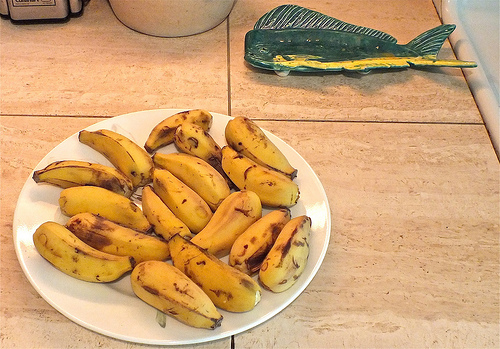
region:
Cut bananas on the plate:
[40, 123, 312, 323]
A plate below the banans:
[46, 108, 326, 320]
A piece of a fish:
[243, 8, 473, 75]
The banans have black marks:
[262, 217, 316, 286]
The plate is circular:
[31, 114, 329, 328]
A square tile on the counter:
[228, 116, 498, 343]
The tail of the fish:
[407, 26, 477, 75]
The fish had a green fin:
[253, 4, 400, 39]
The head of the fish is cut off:
[219, 30, 253, 64]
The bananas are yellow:
[31, 110, 322, 330]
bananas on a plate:
[7, 103, 342, 347]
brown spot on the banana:
[230, 201, 253, 219]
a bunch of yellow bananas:
[29, 111, 314, 334]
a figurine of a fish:
[238, 6, 476, 77]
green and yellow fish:
[240, 5, 481, 86]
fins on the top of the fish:
[253, 1, 403, 42]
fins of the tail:
[408, 17, 479, 79]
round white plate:
[9, 106, 332, 347]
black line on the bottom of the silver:
[1, 7, 94, 26]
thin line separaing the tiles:
[230, 109, 488, 127]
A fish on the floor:
[241, 7, 482, 72]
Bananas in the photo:
[30, 110, 300, 320]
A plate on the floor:
[75, 285, 120, 325]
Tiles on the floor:
[331, 128, 461, 246]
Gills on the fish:
[262, 4, 375, 36]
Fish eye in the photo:
[257, 44, 269, 54]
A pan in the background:
[105, 6, 231, 33]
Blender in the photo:
[0, 0, 81, 20]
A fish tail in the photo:
[408, 22, 463, 57]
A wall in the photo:
[467, 0, 498, 100]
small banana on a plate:
[72, 123, 159, 191]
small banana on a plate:
[53, 179, 150, 235]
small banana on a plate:
[70, 208, 175, 265]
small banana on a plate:
[29, 217, 136, 290]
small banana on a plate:
[122, 253, 227, 335]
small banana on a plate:
[166, 231, 265, 316]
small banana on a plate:
[255, 208, 318, 300]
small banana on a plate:
[225, 203, 293, 275]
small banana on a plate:
[188, 185, 265, 258]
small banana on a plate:
[216, 143, 307, 213]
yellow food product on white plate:
[43, 103, 310, 331]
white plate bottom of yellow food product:
[58, 288, 137, 340]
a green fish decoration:
[244, 8, 475, 77]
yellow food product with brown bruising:
[38, 98, 314, 324]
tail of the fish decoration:
[411, 18, 478, 103]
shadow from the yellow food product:
[28, 252, 135, 304]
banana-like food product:
[38, 103, 337, 332]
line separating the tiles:
[232, 108, 491, 139]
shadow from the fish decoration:
[253, 63, 473, 97]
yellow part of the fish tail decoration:
[413, 52, 473, 75]